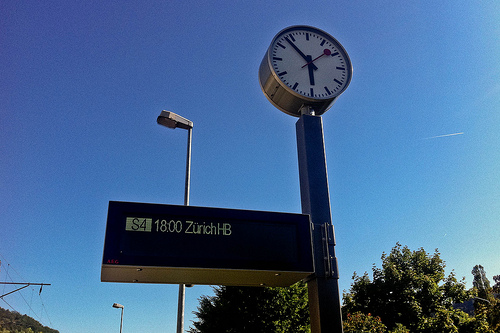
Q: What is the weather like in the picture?
A: It is clear.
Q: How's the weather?
A: It is clear.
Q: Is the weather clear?
A: Yes, it is clear.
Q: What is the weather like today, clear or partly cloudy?
A: It is clear.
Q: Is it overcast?
A: No, it is clear.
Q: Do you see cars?
A: No, there are no cars.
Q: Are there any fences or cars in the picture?
A: No, there are no cars or fences.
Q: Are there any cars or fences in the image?
A: No, there are no cars or fences.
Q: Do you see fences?
A: No, there are no fences.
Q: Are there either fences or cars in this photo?
A: No, there are no fences or cars.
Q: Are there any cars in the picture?
A: No, there are no cars.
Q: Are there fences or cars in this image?
A: No, there are no cars or fences.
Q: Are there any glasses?
A: No, there are no glasses.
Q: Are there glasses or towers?
A: No, there are no glasses or towers.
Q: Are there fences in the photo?
A: No, there are no fences.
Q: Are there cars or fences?
A: No, there are no fences or cars.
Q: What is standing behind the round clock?
A: The tree is standing behind the clock.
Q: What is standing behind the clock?
A: The tree is standing behind the clock.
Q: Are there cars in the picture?
A: No, there are no cars.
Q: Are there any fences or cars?
A: No, there are no cars or fences.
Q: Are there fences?
A: No, there are no fences.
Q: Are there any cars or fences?
A: No, there are no fences or cars.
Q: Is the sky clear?
A: Yes, the sky is clear.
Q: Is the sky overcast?
A: No, the sky is clear.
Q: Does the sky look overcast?
A: No, the sky is clear.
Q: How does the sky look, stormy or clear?
A: The sky is clear.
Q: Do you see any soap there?
A: No, there are no soaps.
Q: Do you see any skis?
A: No, there are no skis.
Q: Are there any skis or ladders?
A: No, there are no skis or ladders.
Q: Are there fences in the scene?
A: No, there are no fences.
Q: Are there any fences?
A: No, there are no fences.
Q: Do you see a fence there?
A: No, there are no fences.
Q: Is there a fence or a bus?
A: No, there are no fences or buses.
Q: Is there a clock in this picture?
A: Yes, there is a clock.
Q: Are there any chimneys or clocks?
A: Yes, there is a clock.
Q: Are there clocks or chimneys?
A: Yes, there is a clock.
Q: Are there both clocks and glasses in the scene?
A: No, there is a clock but no glasses.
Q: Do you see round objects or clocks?
A: Yes, there is a round clock.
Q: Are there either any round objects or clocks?
A: Yes, there is a round clock.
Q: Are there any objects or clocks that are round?
A: Yes, the clock is round.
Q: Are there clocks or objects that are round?
A: Yes, the clock is round.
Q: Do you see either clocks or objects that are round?
A: Yes, the clock is round.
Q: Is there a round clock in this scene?
A: Yes, there is a round clock.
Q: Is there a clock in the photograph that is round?
A: Yes, there is a clock that is round.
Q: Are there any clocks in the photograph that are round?
A: Yes, there is a clock that is round.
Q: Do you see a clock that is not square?
A: Yes, there is a round clock.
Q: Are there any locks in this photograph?
A: No, there are no locks.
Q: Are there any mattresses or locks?
A: No, there are no locks or mattresses.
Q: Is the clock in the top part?
A: Yes, the clock is in the top of the image.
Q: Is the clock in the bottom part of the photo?
A: No, the clock is in the top of the image.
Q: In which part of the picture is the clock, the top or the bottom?
A: The clock is in the top of the image.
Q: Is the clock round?
A: Yes, the clock is round.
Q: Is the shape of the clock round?
A: Yes, the clock is round.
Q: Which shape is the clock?
A: The clock is round.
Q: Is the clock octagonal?
A: No, the clock is round.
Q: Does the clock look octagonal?
A: No, the clock is round.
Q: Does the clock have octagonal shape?
A: No, the clock is round.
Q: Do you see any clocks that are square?
A: No, there is a clock but it is round.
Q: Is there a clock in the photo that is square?
A: No, there is a clock but it is round.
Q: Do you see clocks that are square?
A: No, there is a clock but it is round.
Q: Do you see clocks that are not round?
A: No, there is a clock but it is round.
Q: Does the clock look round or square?
A: The clock is round.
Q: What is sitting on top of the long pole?
A: The clock is sitting on top of the pole.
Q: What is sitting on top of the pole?
A: The clock is sitting on top of the pole.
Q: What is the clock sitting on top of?
A: The clock is sitting on top of the pole.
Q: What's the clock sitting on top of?
A: The clock is sitting on top of the pole.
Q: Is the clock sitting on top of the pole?
A: Yes, the clock is sitting on top of the pole.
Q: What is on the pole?
A: The clock is on the pole.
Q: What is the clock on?
A: The clock is on the pole.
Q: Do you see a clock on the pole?
A: Yes, there is a clock on the pole.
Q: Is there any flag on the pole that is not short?
A: No, there is a clock on the pole.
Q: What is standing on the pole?
A: The clock is standing on the pole.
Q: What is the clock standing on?
A: The clock is standing on the pole.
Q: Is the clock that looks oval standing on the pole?
A: Yes, the clock is standing on the pole.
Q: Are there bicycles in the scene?
A: No, there are no bicycles.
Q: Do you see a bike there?
A: No, there are no bikes.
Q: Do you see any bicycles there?
A: No, there are no bicycles.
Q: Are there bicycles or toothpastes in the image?
A: No, there are no bicycles or toothpastes.